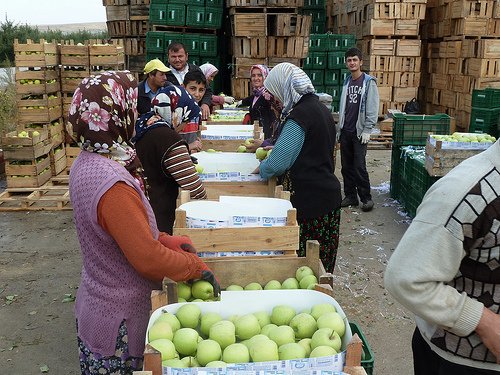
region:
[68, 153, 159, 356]
a lavender sweater vest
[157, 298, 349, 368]
a full box of green apples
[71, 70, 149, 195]
brown floral head wrap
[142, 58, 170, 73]
a yellow ball cap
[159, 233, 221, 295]
a pair of red and black gloves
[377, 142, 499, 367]
a light sweater with brown stained glass design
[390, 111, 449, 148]
green plastic crate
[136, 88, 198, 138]
a blue floral head wrap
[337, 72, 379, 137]
grey sweater shirt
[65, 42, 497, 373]
people sorting through apples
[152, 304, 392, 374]
wooden crate filled with fruit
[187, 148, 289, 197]
wooden crate filled with fruit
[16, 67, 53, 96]
wooden crate filled with fruit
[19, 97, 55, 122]
wooden crate filled with fruit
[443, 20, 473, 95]
stack of wooden crates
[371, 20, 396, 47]
stack of wooden crates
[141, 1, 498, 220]
Green crates stacked up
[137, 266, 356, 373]
A box of apples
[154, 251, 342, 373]
Light green apples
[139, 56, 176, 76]
A yellow ball cap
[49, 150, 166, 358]
A light purple long vest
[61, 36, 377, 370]
People sorting through boxes of apples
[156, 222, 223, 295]
Red and grey gloves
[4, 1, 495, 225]
Stacked wooden crates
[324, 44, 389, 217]
A guy standing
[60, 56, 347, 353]
Women wearing scarves over their heads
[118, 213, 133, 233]
woman wearing orange sweater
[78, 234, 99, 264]
woman wearing purple sweater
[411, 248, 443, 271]
man wearing off white sweater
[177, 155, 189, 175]
woman wearing plaid shirt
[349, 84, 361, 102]
white lettering on shirt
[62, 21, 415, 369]
the people are sorting fruit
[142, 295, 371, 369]
green apples in a box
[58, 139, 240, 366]
she is wearing a purple sweater vest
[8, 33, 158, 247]
wooden crates stacked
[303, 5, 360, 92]
green plastic crates are in a pile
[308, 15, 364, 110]
green plastic crates are in a stack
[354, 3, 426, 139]
a tall stack of wooden crates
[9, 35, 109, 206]
crates of apples are stacked high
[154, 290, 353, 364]
apples in the box.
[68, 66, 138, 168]
The person have scarf over head.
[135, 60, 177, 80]
The man is wearing a cap.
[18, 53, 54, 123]
Apples in the crates.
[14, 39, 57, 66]
wood crate is brown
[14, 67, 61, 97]
wood crate is brown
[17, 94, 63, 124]
wood crate is brown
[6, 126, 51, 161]
wood crate is brown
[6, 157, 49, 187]
wood crate is brown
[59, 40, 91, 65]
wood crate is brown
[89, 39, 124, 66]
wood crate is brown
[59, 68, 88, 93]
wood crate is brown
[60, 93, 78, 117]
wood crate is brown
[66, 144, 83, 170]
wood crate is brown